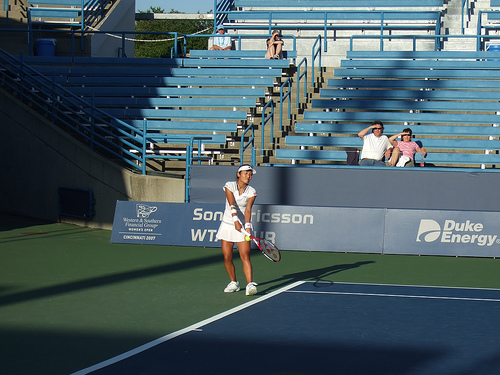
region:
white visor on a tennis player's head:
[236, 164, 257, 176]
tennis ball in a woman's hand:
[242, 236, 252, 242]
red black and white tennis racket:
[234, 225, 284, 263]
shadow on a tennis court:
[236, 258, 380, 296]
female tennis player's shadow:
[232, 257, 377, 295]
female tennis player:
[213, 163, 283, 297]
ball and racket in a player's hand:
[214, 163, 281, 298]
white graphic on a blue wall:
[133, 203, 158, 218]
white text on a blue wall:
[120, 231, 160, 240]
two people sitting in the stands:
[355, 119, 428, 167]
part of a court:
[273, 282, 310, 329]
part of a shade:
[336, 335, 361, 365]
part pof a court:
[341, 308, 368, 340]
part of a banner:
[303, 234, 324, 259]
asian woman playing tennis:
[216, 161, 281, 296]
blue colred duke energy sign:
[388, 211, 498, 257]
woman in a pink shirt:
[393, 128, 425, 164]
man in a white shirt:
[363, 120, 389, 165]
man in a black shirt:
[266, 34, 287, 57]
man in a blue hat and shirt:
[213, 23, 230, 51]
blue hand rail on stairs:
[259, 104, 277, 156]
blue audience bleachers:
[345, 46, 492, 101]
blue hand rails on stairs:
[279, 82, 294, 132]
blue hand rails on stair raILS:
[312, 35, 324, 85]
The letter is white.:
[186, 200, 206, 226]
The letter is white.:
[186, 225, 208, 243]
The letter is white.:
[205, 223, 218, 247]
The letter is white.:
[438, 215, 458, 231]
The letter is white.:
[438, 228, 453, 248]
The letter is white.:
[201, 207, 215, 222]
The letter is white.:
[455, 219, 468, 236]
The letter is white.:
[462, 216, 474, 236]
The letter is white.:
[474, 220, 487, 235]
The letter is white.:
[449, 230, 461, 246]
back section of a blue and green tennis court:
[3, 223, 499, 373]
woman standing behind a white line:
[69, 162, 301, 374]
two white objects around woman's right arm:
[227, 200, 241, 225]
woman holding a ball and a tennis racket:
[238, 225, 280, 265]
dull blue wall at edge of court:
[111, 166, 498, 271]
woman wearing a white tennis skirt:
[214, 219, 251, 241]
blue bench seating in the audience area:
[6, 1, 499, 164]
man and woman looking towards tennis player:
[216, 120, 426, 295]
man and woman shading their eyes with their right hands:
[356, 121, 412, 151]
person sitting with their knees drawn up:
[264, 28, 284, 60]